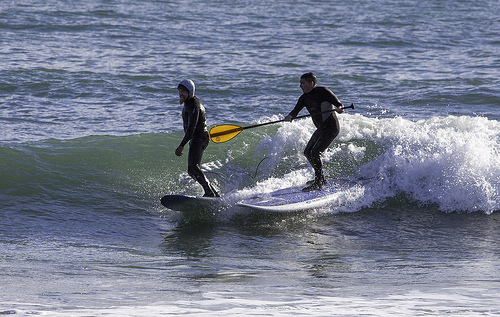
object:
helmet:
[178, 79, 196, 97]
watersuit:
[289, 86, 344, 192]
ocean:
[91, 14, 266, 113]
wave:
[256, 111, 494, 197]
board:
[159, 189, 235, 212]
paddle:
[209, 102, 355, 143]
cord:
[248, 156, 283, 198]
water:
[386, 116, 460, 206]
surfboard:
[235, 176, 377, 215]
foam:
[398, 136, 498, 206]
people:
[284, 72, 345, 192]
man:
[174, 78, 222, 197]